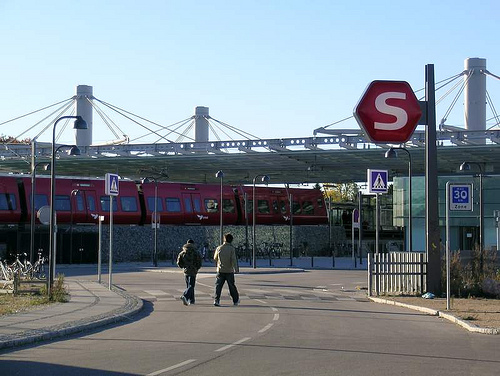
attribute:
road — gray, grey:
[151, 305, 373, 374]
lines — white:
[174, 341, 232, 372]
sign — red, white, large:
[356, 81, 415, 149]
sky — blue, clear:
[6, 1, 445, 60]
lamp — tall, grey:
[43, 115, 90, 305]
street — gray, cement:
[118, 318, 333, 365]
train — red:
[7, 175, 327, 214]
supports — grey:
[70, 84, 108, 154]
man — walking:
[205, 220, 247, 308]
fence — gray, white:
[360, 247, 429, 300]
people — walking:
[164, 225, 246, 308]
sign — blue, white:
[447, 181, 473, 216]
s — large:
[374, 92, 405, 136]